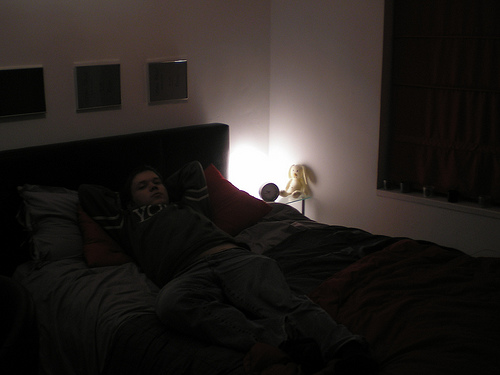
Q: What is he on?
A: Bed.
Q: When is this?
A: Night.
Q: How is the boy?
A: Lying.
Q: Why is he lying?
A: Tired.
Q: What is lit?
A: Lamp.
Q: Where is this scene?
A: In a bedroom.